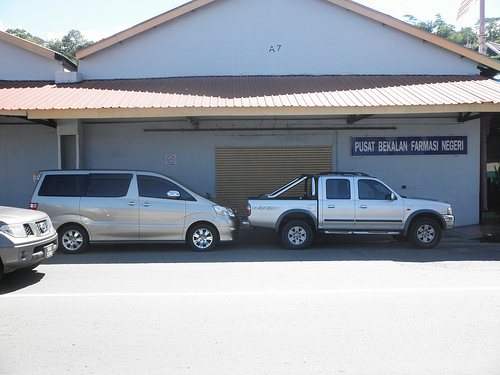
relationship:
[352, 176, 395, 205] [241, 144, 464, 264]
window on truck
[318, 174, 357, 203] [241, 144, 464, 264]
window on truck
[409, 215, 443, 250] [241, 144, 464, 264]
tire on truck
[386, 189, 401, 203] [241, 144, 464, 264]
mirror on truck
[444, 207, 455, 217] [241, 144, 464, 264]
light on truck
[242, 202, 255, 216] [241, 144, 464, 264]
light on truck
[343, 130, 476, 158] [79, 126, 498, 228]
sign on wall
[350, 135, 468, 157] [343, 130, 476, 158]
sign on sign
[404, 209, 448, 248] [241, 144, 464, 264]
tire on truck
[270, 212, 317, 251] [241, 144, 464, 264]
tire on truck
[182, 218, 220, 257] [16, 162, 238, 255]
tire on car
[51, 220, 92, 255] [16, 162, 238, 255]
tire on car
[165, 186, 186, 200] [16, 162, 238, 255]
mirror on car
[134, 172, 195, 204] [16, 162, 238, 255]
window on car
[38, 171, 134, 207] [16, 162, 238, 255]
window on car